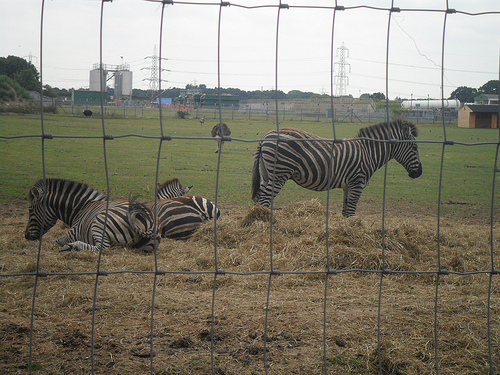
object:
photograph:
[0, 0, 500, 374]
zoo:
[1, 0, 500, 367]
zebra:
[20, 173, 159, 259]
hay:
[0, 198, 498, 374]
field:
[0, 103, 498, 374]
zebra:
[243, 115, 422, 223]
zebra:
[145, 176, 225, 243]